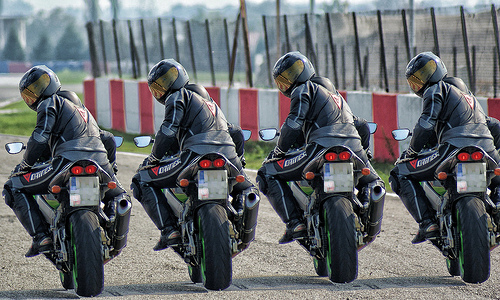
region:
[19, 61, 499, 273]
the four motorcycle riders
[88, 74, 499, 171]
the red and white wall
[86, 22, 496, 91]
the fence in the background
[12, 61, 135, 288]
the rider on the left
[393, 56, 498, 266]
the rider on the right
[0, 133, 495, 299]
the dirt road they are riding on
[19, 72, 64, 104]
the left rider's helmet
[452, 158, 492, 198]
the right rider's license plate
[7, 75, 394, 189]
grass in the background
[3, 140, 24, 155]
the rear view mirror of the left rider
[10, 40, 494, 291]
four men on motorcycles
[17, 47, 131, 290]
man on a motorcycle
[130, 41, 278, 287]
man on a motorcycle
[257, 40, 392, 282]
man on a motorcycle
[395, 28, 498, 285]
man on a motorcycle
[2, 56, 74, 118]
man wearing a motorcycle helmet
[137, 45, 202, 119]
man wearing a motorcycle helmet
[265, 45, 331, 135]
man wearing a motorcycle helmet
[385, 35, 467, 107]
man wearing a motorcycle helmet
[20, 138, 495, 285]
four motorcycles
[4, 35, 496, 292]
four riders on motorcycles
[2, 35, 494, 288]
a group of motorcyclists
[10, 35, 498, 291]
quartet of cycle riders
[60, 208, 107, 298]
green and black rear tire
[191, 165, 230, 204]
place where a license plate should be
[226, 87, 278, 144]
red and white striped barrier tarp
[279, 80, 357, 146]
black leather cycle jacket with red and white logo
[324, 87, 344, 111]
inverted red and white triangle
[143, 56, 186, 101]
black helmet with reflective face shield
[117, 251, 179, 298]
fine gravel course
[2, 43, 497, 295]
Four people on motorcycles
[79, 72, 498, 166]
A red and white barrier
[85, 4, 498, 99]
Chain link on top of the barrier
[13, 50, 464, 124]
The riders are looking back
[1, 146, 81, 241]
Black pants with a grey stripe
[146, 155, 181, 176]
A red and white logo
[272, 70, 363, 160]
A grey and black jacket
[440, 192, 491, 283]
Green and black tires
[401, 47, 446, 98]
A helmet with mirrored visor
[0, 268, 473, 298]
Shadows from the motorcycles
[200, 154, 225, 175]
Rear lights in the photo.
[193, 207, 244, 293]
Motor cycle wheel in the photo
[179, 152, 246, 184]
Motor cycle in the photo.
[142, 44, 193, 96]
A helmet in the photo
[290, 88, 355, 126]
A black jacket in the photo.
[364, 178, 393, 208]
Exhaust pipe in the photo.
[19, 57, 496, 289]
Motor cycle riders in the photo.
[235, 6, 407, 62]
Wooden poles in the photo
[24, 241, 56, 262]
Black shoe in the photo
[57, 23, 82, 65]
Tree in the photo.